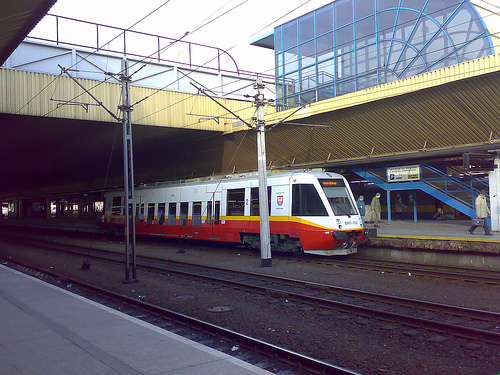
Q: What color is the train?
A: White and red.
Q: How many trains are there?
A: One.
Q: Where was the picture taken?
A: The train station.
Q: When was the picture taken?
A: Daytime.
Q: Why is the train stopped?
A: Passengers are getting off.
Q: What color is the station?
A: Blue.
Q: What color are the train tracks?
A: Black.